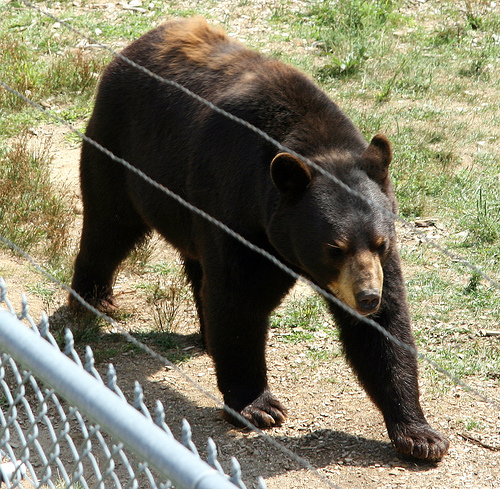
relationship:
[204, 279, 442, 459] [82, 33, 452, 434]
legs of bear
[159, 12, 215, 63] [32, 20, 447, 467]
fur on bear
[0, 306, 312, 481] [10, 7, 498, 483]
shadow on ground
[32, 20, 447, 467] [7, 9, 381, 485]
bear outside fence